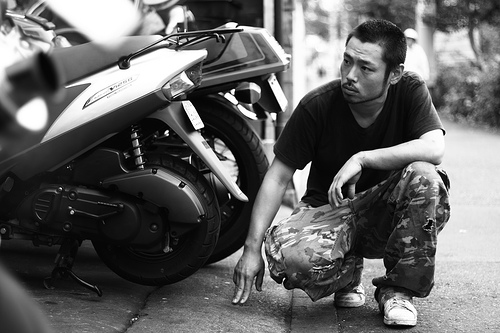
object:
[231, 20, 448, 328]
man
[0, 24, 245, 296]
bike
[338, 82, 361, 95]
mustache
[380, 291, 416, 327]
sneaker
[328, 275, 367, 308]
sneaker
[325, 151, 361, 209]
hand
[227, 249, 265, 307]
hand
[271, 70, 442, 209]
t shirt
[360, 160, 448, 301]
leg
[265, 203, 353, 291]
leg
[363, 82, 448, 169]
arm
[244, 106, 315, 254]
arm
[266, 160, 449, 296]
pants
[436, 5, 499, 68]
trees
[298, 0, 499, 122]
background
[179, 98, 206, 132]
license plate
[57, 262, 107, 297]
kick stand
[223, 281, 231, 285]
pebbles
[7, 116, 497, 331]
ground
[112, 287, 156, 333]
groove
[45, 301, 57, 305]
oil slick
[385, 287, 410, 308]
laces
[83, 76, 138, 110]
logo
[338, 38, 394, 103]
face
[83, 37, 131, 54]
shine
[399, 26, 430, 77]
man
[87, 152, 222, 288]
tire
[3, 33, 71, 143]
exhaust pipe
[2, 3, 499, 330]
photo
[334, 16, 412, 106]
head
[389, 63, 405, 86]
ear